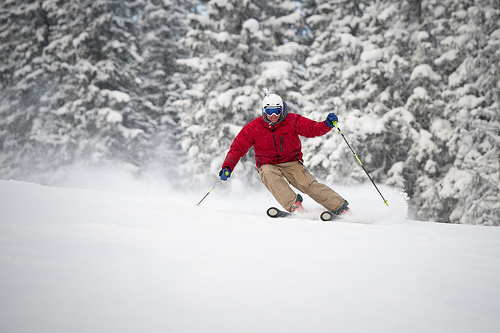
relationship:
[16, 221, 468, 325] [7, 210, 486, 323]
ground covered in snow